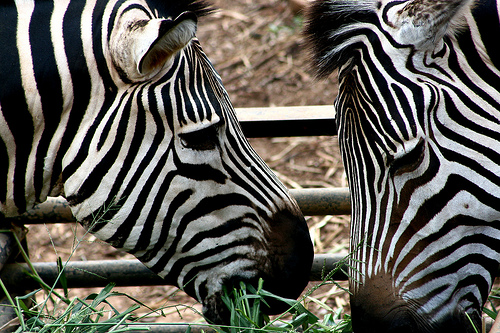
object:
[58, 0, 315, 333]
head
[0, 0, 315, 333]
zebra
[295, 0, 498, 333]
zebra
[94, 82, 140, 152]
stripes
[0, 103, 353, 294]
fence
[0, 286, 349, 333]
grass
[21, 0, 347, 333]
ground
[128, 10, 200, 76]
ear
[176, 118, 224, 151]
eye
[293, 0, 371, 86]
mane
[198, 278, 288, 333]
mouth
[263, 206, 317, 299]
nose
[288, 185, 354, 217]
bars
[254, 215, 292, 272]
dirt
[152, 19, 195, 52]
hair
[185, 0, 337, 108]
dirt